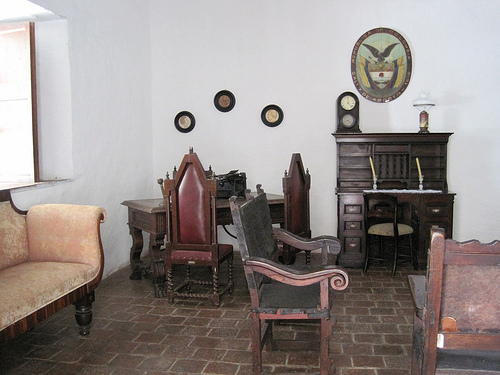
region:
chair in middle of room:
[230, 190, 350, 362]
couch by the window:
[0, 187, 113, 355]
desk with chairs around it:
[132, 152, 327, 304]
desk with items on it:
[331, 124, 458, 265]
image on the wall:
[333, 23, 425, 97]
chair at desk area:
[358, 190, 416, 275]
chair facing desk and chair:
[408, 224, 498, 374]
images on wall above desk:
[147, 85, 291, 137]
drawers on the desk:
[345, 195, 362, 262]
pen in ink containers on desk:
[368, 143, 430, 196]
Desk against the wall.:
[331, 128, 456, 277]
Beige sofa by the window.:
[0, 190, 107, 370]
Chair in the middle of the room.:
[224, 184, 353, 374]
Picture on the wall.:
[347, 28, 411, 108]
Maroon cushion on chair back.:
[160, 156, 217, 246]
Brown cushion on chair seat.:
[367, 218, 413, 238]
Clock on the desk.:
[331, 90, 366, 132]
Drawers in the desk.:
[341, 200, 361, 253]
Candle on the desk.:
[411, 155, 426, 190]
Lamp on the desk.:
[409, 90, 437, 132]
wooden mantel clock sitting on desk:
[331, 88, 361, 138]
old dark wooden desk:
[330, 126, 457, 276]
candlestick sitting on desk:
[412, 153, 425, 193]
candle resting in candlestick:
[365, 155, 378, 175]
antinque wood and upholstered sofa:
[0, 186, 106, 342]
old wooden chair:
[160, 145, 233, 308]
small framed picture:
[172, 108, 193, 133]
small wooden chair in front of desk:
[360, 187, 416, 277]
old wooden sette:
[225, 177, 347, 372]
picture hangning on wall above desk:
[347, 24, 416, 105]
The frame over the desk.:
[351, 25, 414, 102]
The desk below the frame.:
[332, 129, 454, 269]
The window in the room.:
[0, 19, 45, 186]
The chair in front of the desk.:
[357, 188, 418, 282]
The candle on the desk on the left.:
[368, 155, 377, 187]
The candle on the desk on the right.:
[415, 153, 425, 186]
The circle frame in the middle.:
[212, 90, 235, 109]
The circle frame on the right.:
[261, 105, 283, 125]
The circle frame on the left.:
[175, 111, 195, 132]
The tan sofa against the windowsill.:
[0, 189, 109, 356]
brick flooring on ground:
[149, 318, 233, 374]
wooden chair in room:
[424, 227, 498, 372]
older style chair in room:
[157, 149, 236, 300]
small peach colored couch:
[0, 194, 103, 355]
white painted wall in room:
[94, 26, 150, 148]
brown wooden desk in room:
[339, 130, 454, 267]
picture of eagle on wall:
[348, 29, 411, 103]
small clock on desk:
[334, 88, 363, 131]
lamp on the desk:
[408, 92, 438, 130]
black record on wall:
[257, 97, 287, 130]